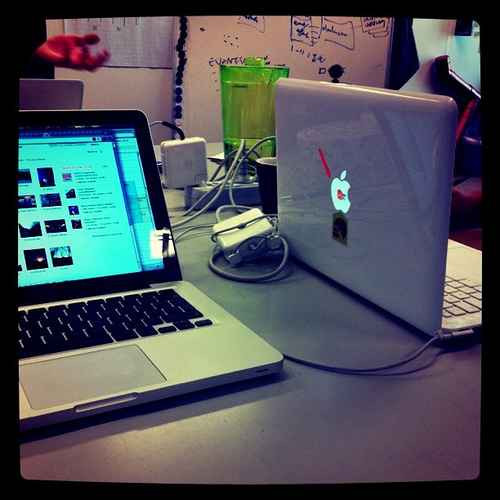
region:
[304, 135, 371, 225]
An apple logo.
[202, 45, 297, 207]
A green cup.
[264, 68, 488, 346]
An apple laptop.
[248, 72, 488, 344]
The laptop is white.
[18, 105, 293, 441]
The laptop is on.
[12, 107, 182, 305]
The screen is bright.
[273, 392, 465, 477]
The table is gray.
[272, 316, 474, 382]
A power cord from the laptop.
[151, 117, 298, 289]
A lot of wires.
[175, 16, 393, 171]
A board is in the background.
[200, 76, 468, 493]
a computer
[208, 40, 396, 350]
a computer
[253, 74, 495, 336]
a computer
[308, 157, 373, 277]
The logo is visible.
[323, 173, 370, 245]
The logo is visible.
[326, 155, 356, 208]
The logo is visible.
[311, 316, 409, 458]
A wire is visible.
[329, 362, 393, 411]
A wire is visible.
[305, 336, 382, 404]
A wire is visible.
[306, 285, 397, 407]
A wire is visible.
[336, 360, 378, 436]
A wire is visible.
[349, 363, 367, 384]
A wire is visible.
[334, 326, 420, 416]
A wire is visible.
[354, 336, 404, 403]
A wire is visible.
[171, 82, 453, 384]
a computer on a table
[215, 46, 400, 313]
a computer on a table